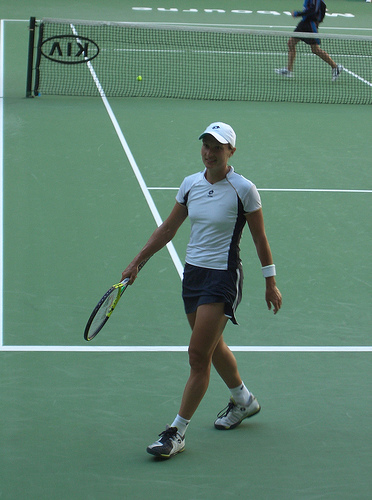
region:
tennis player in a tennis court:
[0, 0, 370, 498]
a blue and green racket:
[72, 271, 141, 344]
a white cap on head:
[195, 113, 241, 151]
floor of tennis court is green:
[2, 0, 364, 497]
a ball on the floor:
[126, 64, 149, 92]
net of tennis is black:
[16, 14, 369, 111]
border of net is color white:
[34, 13, 367, 41]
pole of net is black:
[19, 14, 38, 99]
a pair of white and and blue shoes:
[137, 394, 268, 460]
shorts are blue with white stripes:
[171, 265, 250, 325]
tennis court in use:
[0, 0, 370, 499]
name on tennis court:
[130, 3, 357, 24]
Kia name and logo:
[37, 32, 102, 65]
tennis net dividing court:
[20, 15, 368, 106]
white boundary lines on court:
[1, 17, 369, 356]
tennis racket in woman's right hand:
[81, 275, 134, 341]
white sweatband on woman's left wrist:
[260, 264, 276, 277]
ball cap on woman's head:
[198, 121, 239, 149]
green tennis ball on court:
[133, 73, 143, 82]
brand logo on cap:
[211, 125, 220, 131]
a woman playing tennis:
[77, 98, 290, 464]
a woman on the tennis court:
[83, 101, 295, 468]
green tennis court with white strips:
[0, 0, 369, 496]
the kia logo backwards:
[35, 28, 108, 62]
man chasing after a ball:
[124, 0, 358, 84]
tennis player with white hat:
[83, 115, 289, 456]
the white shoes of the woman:
[149, 376, 263, 459]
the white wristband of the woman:
[255, 264, 283, 279]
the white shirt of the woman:
[175, 169, 263, 279]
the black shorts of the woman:
[174, 249, 254, 327]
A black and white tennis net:
[26, 17, 370, 105]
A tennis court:
[1, 2, 370, 498]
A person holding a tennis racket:
[78, 115, 288, 459]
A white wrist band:
[256, 255, 277, 279]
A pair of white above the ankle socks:
[163, 378, 254, 429]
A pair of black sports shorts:
[181, 261, 245, 326]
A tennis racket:
[73, 248, 158, 338]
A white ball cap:
[198, 120, 239, 150]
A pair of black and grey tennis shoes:
[144, 393, 258, 458]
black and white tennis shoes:
[144, 425, 185, 456]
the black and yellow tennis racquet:
[81, 279, 125, 341]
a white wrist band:
[261, 264, 275, 279]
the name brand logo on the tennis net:
[39, 33, 100, 64]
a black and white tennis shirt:
[174, 165, 261, 268]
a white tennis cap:
[198, 120, 236, 147]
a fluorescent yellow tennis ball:
[133, 73, 141, 83]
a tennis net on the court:
[25, 15, 370, 103]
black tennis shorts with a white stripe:
[181, 261, 242, 321]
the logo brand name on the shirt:
[206, 187, 213, 198]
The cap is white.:
[201, 117, 245, 142]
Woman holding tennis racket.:
[97, 268, 145, 343]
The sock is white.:
[168, 410, 196, 433]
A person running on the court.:
[281, 3, 334, 92]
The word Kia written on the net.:
[34, 33, 119, 70]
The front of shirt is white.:
[184, 188, 231, 266]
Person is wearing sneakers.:
[142, 415, 227, 460]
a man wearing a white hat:
[198, 116, 244, 151]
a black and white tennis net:
[145, 20, 345, 113]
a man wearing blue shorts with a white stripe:
[183, 265, 243, 317]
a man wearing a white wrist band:
[261, 259, 277, 280]